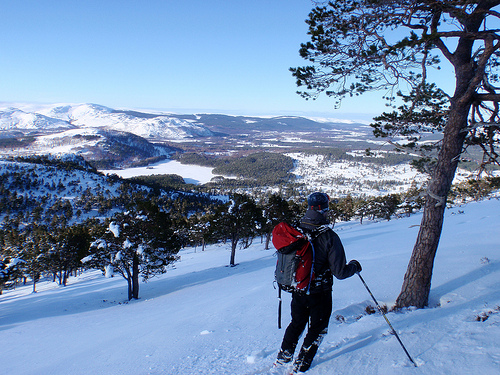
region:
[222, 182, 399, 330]
MAN SKIING ON SLOPE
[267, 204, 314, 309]
RED BACKPACK ON SKIER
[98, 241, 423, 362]
SNOW COVERING GROUND ON SLOPE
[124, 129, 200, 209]
SNOW LAYING ON MOUNTAINS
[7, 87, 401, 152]
SNOWY MOUNTAINS IN DISTANCE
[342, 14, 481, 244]
TALL TREE GROWING ON LEFT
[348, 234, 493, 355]
SKI POLE IN HAND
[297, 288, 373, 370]
SHADOW OF MAN ON SNOW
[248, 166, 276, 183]
TREES GROWING ON MOUNTAINS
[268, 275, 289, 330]
STRAP HANGING FROM BACKPACK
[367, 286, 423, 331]
part of a hooker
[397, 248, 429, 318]
part of a stem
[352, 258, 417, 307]
part of a hooker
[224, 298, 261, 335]
part of a stand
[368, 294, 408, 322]
part of a stand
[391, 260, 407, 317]
part of a tree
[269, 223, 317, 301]
Red backpack being carried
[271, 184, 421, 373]
skier standing on a mountain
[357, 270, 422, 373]
ski pole standing in the snow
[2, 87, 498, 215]
mountains covered in snow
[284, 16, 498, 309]
Tree on the side of a mountain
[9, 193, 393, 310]
Tree line with snow on the branches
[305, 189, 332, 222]
ski helmet on a man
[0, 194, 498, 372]
Snow on the side of a mountain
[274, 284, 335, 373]
ski pants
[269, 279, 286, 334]
pick hanging from a backpack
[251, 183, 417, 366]
Man on a hill.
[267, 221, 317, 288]
Red backpack on the man.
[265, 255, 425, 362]
Black ski poles with the man.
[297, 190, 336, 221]
Winter cap on the man.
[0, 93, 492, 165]
Snow capped mountains in the background.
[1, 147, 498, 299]
Snow covered trees in the background.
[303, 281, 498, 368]
Shadow of the man on the hill.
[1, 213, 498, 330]
Shadows of the trees on the ground.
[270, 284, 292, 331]
Strap from backpack hanging down.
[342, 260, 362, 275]
Gloves on the man.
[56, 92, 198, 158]
This is a mountain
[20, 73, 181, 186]
This is the highest peak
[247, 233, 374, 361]
This is a backpack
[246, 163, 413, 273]
This is a helmet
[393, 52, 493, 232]
This is a tree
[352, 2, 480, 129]
The tree has no leaves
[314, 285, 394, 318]
This is a ski pole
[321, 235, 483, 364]
The pole is metal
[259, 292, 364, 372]
These are dark pants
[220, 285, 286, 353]
The pants are black